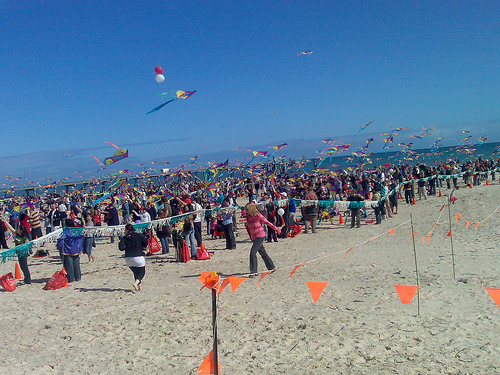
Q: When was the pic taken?
A: During the day.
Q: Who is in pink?
A: Woman crossing.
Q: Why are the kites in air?
A: There is wind.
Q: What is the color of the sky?
A: Blue.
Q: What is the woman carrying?
A: A bag.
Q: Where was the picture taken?
A: On a beach.